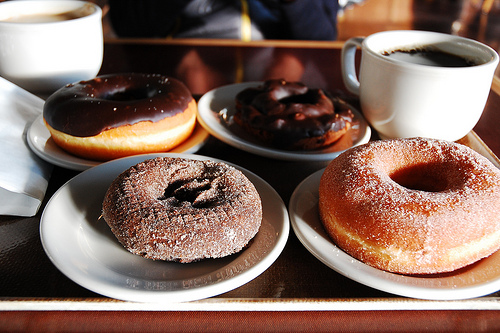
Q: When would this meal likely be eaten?
A: Breakfast.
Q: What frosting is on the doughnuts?
A: Chocolate.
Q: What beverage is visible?
A: Coffee.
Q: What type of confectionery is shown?
A: Doughnuts.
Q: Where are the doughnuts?
A: On plates.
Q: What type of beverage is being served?
A: Coffee.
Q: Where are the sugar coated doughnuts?
A: In front of the other doughnuts.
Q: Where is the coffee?
A: In a cup.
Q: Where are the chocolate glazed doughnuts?
A: Behind the sugar doughnuts.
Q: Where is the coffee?
A: Behind the doughnuts.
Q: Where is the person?
A: Behind the doughnuts.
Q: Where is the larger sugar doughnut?
A: On the right.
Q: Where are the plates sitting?
A: On a table.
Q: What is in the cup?
A: Coffee.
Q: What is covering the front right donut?
A: Sugar.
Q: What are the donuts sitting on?
A: Plates.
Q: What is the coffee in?
A: Cup.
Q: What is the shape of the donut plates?
A: Circle.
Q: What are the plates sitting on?
A: Table.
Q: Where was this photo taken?
A: Coffee Shop.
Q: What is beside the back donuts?
A: Coffee.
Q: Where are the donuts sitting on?
A: They are on a saucer.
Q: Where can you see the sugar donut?
A: On the right front of table.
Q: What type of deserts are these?
A: They are donuts.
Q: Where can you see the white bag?
A: Next to chocolate covered donut.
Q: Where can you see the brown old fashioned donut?
A: On the front left side of table.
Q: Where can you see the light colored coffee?
A: Cup next to chocolate frosted donut.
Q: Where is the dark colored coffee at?
A: In the mcup to the right.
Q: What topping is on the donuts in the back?
A: Chocolate.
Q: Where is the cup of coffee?
A: Behind the donuts.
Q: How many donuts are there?
A: Four.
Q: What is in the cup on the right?
A: Coffee.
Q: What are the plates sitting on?
A: A table.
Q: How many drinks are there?
A: Two.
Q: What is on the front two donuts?
A: Sugar.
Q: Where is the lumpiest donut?
A: In the top right.